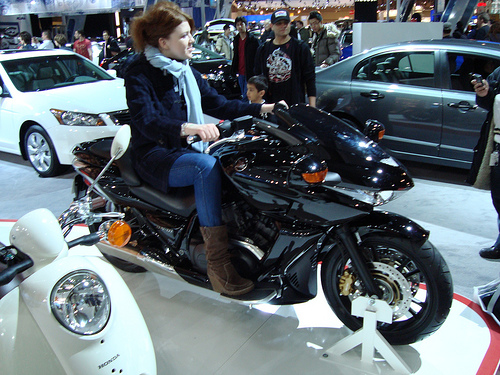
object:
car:
[1, 50, 132, 176]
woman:
[122, 1, 289, 296]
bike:
[70, 102, 455, 347]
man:
[253, 7, 316, 112]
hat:
[270, 9, 290, 28]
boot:
[196, 223, 253, 297]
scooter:
[0, 123, 161, 375]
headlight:
[50, 269, 112, 336]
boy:
[244, 75, 269, 107]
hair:
[247, 76, 267, 92]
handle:
[360, 90, 382, 101]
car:
[303, 36, 500, 177]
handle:
[446, 102, 475, 113]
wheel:
[321, 229, 453, 349]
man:
[72, 28, 93, 65]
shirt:
[73, 40, 92, 60]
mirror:
[109, 123, 132, 159]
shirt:
[256, 38, 315, 102]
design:
[265, 47, 291, 81]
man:
[230, 14, 262, 100]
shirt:
[236, 35, 246, 76]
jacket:
[230, 34, 258, 75]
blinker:
[301, 167, 329, 186]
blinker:
[377, 126, 385, 140]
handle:
[186, 121, 230, 146]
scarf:
[143, 45, 209, 154]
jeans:
[169, 153, 223, 223]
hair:
[129, 0, 194, 51]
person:
[467, 64, 499, 260]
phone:
[473, 72, 484, 91]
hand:
[471, 77, 490, 99]